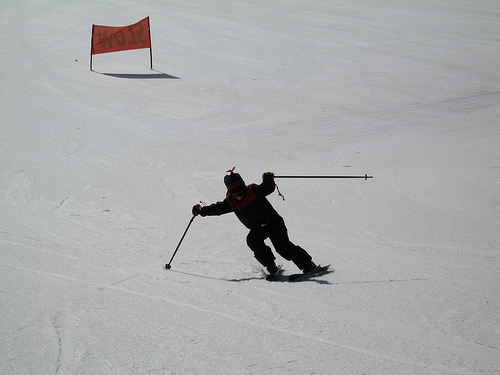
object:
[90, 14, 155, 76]
orange slow sign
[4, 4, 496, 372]
snow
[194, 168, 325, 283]
skier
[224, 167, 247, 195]
hat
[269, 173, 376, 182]
ski pole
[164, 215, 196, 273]
ski pole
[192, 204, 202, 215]
hand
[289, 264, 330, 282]
skis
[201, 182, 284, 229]
sweater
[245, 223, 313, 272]
pants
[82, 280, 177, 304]
tracks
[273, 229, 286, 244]
black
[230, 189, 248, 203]
mask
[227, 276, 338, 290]
shadow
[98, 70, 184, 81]
sign shadow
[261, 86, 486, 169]
ski tracks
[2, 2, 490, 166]
slope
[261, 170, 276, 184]
glove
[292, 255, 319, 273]
boots